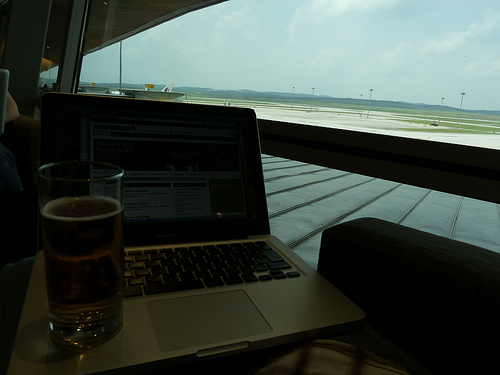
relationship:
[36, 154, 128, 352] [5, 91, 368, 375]
glass on computer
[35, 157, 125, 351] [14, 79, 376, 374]
glass on computer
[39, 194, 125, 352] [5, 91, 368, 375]
beer on computer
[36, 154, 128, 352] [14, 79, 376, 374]
glass sitting on computer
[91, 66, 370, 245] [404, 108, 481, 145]
airport has runway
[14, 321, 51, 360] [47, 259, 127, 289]
light refracting through beer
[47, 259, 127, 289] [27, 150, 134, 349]
beer in glass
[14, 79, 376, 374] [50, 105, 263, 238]
computer has screen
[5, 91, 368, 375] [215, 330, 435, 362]
computer on lap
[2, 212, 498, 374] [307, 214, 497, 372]
chair has arm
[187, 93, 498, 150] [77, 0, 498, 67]
field outside window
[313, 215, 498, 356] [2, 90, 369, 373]
arm next to latop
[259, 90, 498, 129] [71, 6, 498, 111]
field outside window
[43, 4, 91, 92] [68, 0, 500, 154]
beam between window